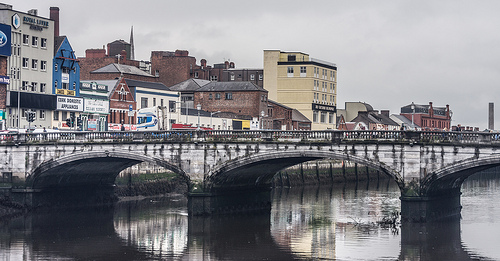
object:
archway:
[206, 155, 404, 204]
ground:
[392, 150, 456, 165]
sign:
[51, 93, 86, 113]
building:
[7, 88, 85, 130]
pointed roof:
[194, 80, 270, 93]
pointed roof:
[169, 77, 210, 91]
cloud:
[94, 0, 466, 27]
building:
[0, 2, 56, 129]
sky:
[0, 1, 497, 131]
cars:
[358, 131, 377, 140]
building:
[397, 100, 454, 133]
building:
[105, 25, 145, 61]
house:
[342, 108, 404, 142]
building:
[48, 5, 85, 133]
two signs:
[55, 92, 112, 115]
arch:
[28, 141, 195, 216]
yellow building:
[258, 47, 340, 131]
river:
[1, 174, 500, 261]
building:
[267, 96, 313, 131]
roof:
[89, 60, 159, 79]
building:
[193, 79, 270, 130]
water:
[435, 203, 499, 258]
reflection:
[438, 168, 500, 261]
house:
[389, 111, 422, 132]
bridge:
[0, 124, 499, 203]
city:
[0, 4, 500, 258]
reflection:
[57, 187, 199, 258]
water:
[263, 203, 330, 251]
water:
[49, 206, 207, 252]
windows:
[224, 92, 234, 100]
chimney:
[381, 110, 390, 118]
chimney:
[358, 111, 368, 113]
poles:
[177, 131, 181, 142]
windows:
[168, 99, 176, 113]